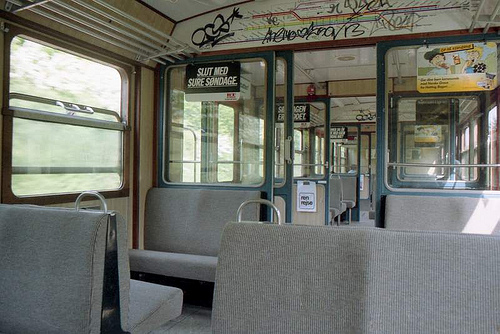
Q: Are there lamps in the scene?
A: No, there are no lamps.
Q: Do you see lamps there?
A: No, there are no lamps.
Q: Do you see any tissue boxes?
A: No, there are no tissue boxes.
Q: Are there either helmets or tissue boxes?
A: No, there are no tissue boxes or helmets.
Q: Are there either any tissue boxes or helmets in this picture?
A: No, there are no tissue boxes or helmets.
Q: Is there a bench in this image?
A: Yes, there is a bench.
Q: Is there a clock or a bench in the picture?
A: Yes, there is a bench.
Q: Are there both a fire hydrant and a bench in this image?
A: No, there is a bench but no fire hydrants.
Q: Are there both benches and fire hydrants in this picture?
A: No, there is a bench but no fire hydrants.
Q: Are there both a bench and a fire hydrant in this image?
A: No, there is a bench but no fire hydrants.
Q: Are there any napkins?
A: No, there are no napkins.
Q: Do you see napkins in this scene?
A: No, there are no napkins.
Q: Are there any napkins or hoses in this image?
A: No, there are no napkins or hoses.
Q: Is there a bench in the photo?
A: Yes, there is a bench.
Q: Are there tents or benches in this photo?
A: Yes, there is a bench.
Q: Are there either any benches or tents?
A: Yes, there is a bench.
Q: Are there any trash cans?
A: No, there are no trash cans.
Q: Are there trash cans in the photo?
A: No, there are no trash cans.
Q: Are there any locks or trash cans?
A: No, there are no trash cans or locks.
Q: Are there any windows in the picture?
A: Yes, there is a window.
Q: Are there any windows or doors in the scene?
A: Yes, there is a window.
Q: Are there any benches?
A: Yes, there is a bench.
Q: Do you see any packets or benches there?
A: Yes, there is a bench.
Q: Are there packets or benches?
A: Yes, there is a bench.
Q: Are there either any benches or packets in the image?
A: Yes, there is a bench.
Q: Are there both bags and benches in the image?
A: No, there is a bench but no bags.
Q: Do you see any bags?
A: No, there are no bags.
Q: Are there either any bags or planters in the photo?
A: No, there are no bags or planters.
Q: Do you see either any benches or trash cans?
A: Yes, there is a bench.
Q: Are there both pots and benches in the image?
A: No, there is a bench but no pots.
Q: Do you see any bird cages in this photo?
A: No, there are no bird cages.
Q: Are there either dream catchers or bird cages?
A: No, there are no bird cages or dream catchers.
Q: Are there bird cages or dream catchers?
A: No, there are no bird cages or dream catchers.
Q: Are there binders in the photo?
A: No, there are no binders.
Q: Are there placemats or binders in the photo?
A: No, there are no binders or placemats.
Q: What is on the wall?
A: The graffiti is on the wall.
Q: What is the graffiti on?
A: The graffiti is on the wall.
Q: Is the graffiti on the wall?
A: Yes, the graffiti is on the wall.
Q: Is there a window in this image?
A: Yes, there is a window.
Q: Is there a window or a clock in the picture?
A: Yes, there is a window.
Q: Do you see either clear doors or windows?
A: Yes, there is a clear window.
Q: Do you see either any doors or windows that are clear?
A: Yes, the window is clear.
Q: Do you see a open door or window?
A: Yes, there is an open window.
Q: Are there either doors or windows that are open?
A: Yes, the window is open.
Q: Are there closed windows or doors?
A: Yes, there is a closed window.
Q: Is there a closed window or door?
A: Yes, there is a closed window.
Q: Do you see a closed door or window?
A: Yes, there is a closed window.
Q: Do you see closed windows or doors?
A: Yes, there is a closed window.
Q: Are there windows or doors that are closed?
A: Yes, the window is closed.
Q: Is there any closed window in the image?
A: Yes, there is a closed window.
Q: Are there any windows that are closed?
A: Yes, there is a window that is closed.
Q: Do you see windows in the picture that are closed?
A: Yes, there is a window that is closed.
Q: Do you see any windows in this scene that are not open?
A: Yes, there is an closed window.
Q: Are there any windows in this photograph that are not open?
A: Yes, there is an closed window.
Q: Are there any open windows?
A: Yes, there is an open window.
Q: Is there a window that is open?
A: Yes, there is a window that is open.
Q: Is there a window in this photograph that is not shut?
A: Yes, there is a open window.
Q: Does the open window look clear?
A: Yes, the window is clear.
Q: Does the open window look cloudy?
A: No, the window is clear.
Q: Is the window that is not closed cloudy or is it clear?
A: The window is clear.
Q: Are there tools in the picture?
A: No, there are no tools.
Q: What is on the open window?
A: The sign is on the window.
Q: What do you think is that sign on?
A: The sign is on the window.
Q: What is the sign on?
A: The sign is on the window.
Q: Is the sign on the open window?
A: Yes, the sign is on the window.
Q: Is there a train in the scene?
A: Yes, there is a train.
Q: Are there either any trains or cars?
A: Yes, there is a train.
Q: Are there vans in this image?
A: No, there are no vans.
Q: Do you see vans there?
A: No, there are no vans.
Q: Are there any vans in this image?
A: No, there are no vans.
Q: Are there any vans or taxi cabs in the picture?
A: No, there are no vans or taxi cabs.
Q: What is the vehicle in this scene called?
A: The vehicle is a train.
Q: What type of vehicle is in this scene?
A: The vehicle is a train.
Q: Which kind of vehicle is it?
A: The vehicle is a train.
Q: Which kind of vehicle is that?
A: That is a train.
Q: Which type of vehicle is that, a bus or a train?
A: That is a train.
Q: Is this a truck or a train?
A: This is a train.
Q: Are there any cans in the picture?
A: No, there are no cans.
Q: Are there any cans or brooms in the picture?
A: No, there are no cans or brooms.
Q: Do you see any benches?
A: Yes, there is a bench.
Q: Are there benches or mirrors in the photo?
A: Yes, there is a bench.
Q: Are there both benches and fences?
A: No, there is a bench but no fences.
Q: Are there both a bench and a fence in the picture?
A: No, there is a bench but no fences.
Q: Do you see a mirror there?
A: No, there are no mirrors.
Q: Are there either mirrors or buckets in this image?
A: No, there are no mirrors or buckets.